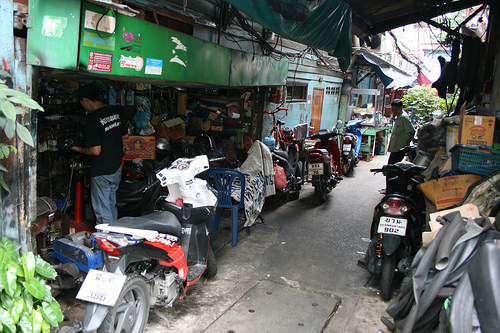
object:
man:
[389, 99, 416, 166]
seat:
[109, 210, 190, 236]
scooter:
[54, 155, 220, 333]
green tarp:
[228, 0, 355, 74]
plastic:
[449, 144, 500, 178]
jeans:
[91, 167, 124, 233]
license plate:
[80, 266, 151, 333]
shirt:
[83, 107, 126, 176]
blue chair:
[194, 168, 250, 247]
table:
[398, 89, 483, 193]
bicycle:
[267, 123, 314, 204]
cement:
[51, 147, 416, 333]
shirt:
[388, 110, 415, 153]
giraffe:
[196, 159, 247, 246]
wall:
[258, 73, 378, 147]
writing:
[100, 113, 121, 132]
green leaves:
[400, 85, 454, 117]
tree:
[0, 237, 68, 332]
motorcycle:
[365, 161, 428, 302]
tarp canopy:
[362, 53, 394, 89]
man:
[71, 83, 130, 233]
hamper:
[52, 231, 104, 280]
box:
[420, 175, 484, 210]